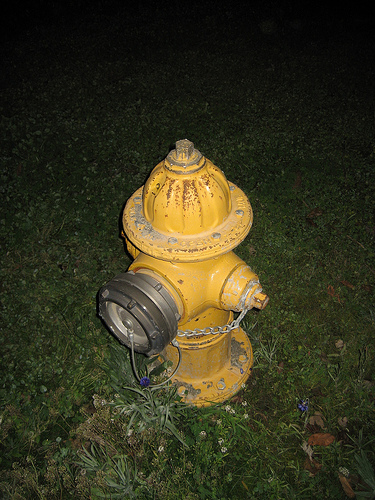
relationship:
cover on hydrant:
[119, 135, 254, 265] [119, 136, 271, 410]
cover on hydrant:
[92, 269, 182, 356] [93, 136, 267, 410]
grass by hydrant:
[258, 272, 348, 434] [112, 141, 256, 387]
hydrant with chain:
[97, 158, 237, 382] [168, 285, 268, 363]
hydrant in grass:
[97, 138, 269, 413] [22, 253, 124, 388]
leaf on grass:
[294, 430, 342, 449] [315, 445, 345, 461]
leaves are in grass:
[293, 402, 368, 498] [0, 4, 372, 498]